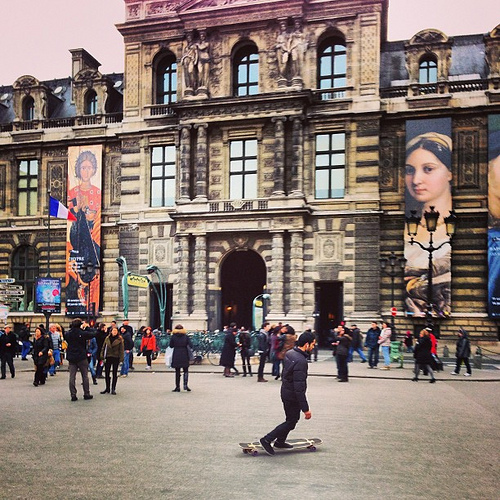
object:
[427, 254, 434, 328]
lamp post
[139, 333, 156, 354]
jacket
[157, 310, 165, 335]
pole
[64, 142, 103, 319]
painting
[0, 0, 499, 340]
building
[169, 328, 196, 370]
jacket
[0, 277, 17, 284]
signs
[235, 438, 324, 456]
skateboard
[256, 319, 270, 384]
people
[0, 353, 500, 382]
sidewalk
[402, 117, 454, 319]
artwork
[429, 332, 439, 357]
coat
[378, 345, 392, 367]
pants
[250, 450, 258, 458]
wheels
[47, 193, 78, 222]
flag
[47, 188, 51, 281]
pole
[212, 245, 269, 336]
doorway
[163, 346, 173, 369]
bag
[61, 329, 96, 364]
coat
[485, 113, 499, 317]
banner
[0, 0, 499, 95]
sky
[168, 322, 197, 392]
person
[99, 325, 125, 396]
person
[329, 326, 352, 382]
person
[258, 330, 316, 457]
man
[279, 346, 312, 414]
jacket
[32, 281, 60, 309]
art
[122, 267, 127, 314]
green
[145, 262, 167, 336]
lamp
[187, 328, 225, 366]
bike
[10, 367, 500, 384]
curb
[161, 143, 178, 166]
windows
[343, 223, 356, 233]
stone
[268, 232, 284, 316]
column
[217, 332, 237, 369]
coat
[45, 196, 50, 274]
flagpole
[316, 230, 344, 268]
decoration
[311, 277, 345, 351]
doorway